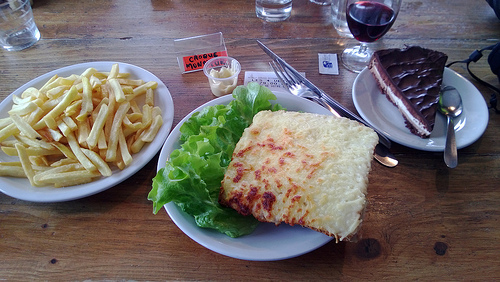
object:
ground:
[366, 141, 499, 281]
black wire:
[445, 41, 499, 77]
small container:
[202, 56, 241, 97]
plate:
[0, 61, 175, 204]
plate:
[351, 62, 490, 152]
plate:
[156, 92, 337, 262]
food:
[365, 44, 448, 140]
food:
[0, 62, 163, 187]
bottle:
[0, 2, 41, 52]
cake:
[367, 44, 449, 140]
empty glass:
[0, 0, 40, 52]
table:
[0, 0, 499, 282]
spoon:
[437, 85, 464, 168]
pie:
[366, 43, 449, 139]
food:
[146, 80, 379, 244]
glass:
[341, 1, 397, 75]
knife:
[254, 39, 391, 149]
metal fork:
[254, 39, 390, 151]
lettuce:
[145, 81, 292, 239]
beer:
[345, 2, 398, 43]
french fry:
[33, 163, 98, 187]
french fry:
[108, 78, 126, 103]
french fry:
[9, 112, 43, 140]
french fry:
[85, 103, 108, 149]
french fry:
[27, 84, 78, 131]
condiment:
[208, 66, 238, 96]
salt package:
[317, 53, 339, 75]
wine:
[345, 1, 397, 42]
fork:
[256, 40, 399, 168]